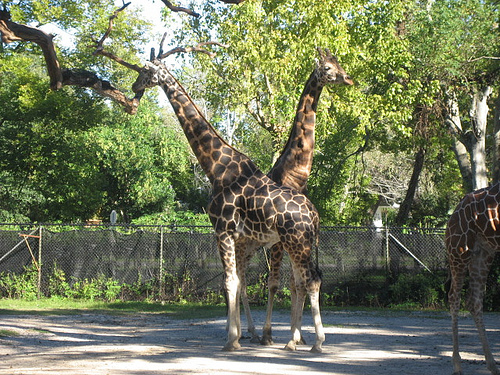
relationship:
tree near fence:
[347, 10, 491, 107] [70, 223, 190, 310]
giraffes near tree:
[127, 46, 375, 285] [347, 10, 491, 107]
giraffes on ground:
[127, 46, 375, 285] [45, 315, 193, 372]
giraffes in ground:
[127, 46, 375, 285] [45, 315, 193, 372]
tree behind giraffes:
[347, 10, 491, 107] [127, 46, 375, 285]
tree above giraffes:
[347, 10, 491, 107] [127, 46, 375, 285]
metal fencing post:
[108, 228, 185, 286] [29, 212, 493, 363]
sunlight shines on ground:
[116, 0, 186, 66] [149, 319, 233, 369]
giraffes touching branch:
[130, 46, 326, 354] [49, 66, 136, 98]